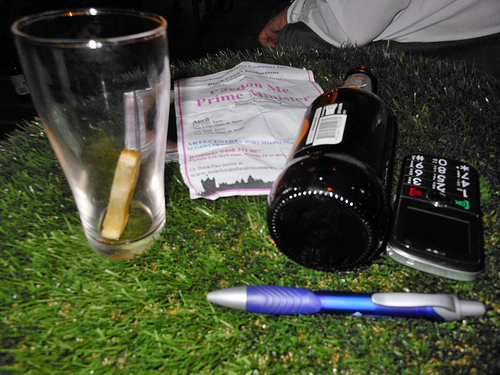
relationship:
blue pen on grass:
[204, 282, 484, 322] [20, 254, 211, 364]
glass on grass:
[9, 8, 171, 261] [12, 234, 199, 364]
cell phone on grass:
[382, 150, 489, 282] [2, 46, 499, 373]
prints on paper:
[184, 59, 311, 197] [174, 61, 326, 201]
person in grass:
[261, 0, 498, 72] [35, 252, 206, 363]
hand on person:
[257, 10, 285, 50] [258, 0, 499, 47]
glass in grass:
[9, 3, 173, 262] [2, 46, 499, 373]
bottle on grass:
[289, 75, 391, 261] [38, 295, 118, 372]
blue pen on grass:
[207, 285, 485, 322] [2, 46, 499, 373]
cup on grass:
[10, 12, 191, 259] [84, 252, 194, 319]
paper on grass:
[184, 65, 314, 197] [2, 46, 499, 373]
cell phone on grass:
[386, 153, 485, 281] [1, 258, 206, 372]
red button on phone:
[407, 182, 423, 198] [387, 137, 481, 280]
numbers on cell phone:
[436, 157, 447, 167] [386, 153, 485, 281]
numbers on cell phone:
[412, 159, 425, 169] [386, 153, 485, 281]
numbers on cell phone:
[459, 168, 472, 180] [386, 153, 485, 281]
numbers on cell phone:
[437, 172, 445, 184] [386, 153, 485, 281]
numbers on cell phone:
[413, 167, 421, 177] [386, 153, 485, 281]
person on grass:
[258, 0, 497, 55] [83, 262, 186, 355]